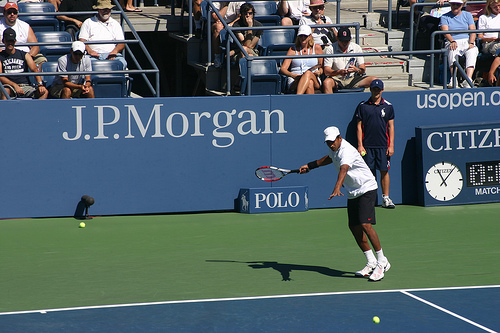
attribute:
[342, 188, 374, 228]
shorts — navy blue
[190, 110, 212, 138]
letter — white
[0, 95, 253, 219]
wall — blue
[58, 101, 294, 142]
name — FAMOUS PERSON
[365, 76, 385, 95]
hat — MANS, BLUE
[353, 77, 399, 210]
guy — wearing blue shorts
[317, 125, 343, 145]
cap — white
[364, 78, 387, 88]
hat — blue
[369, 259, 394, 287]
shoe — white, black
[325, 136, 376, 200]
shirt — white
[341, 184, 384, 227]
shorts — black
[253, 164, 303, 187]
tennis racquet — red, white, black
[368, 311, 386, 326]
tennis ball — yellow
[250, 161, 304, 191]
racket — red, white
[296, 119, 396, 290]
player — white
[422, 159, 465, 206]
clock — white, analog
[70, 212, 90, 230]
ball — tennis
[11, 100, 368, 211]
wall — blue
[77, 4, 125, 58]
man — one 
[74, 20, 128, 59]
shirt — white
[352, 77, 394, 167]
man — one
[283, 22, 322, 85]
woman — one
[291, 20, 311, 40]
cap — white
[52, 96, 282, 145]
name — bank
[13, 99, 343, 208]
background — blue